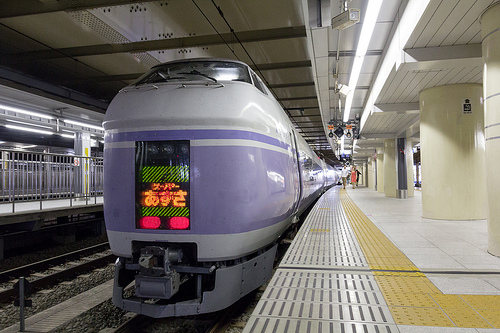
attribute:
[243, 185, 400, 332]
platform — metal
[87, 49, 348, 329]
train — metal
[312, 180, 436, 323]
platform — white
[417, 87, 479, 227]
pillar — round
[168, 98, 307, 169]
stripe — grey